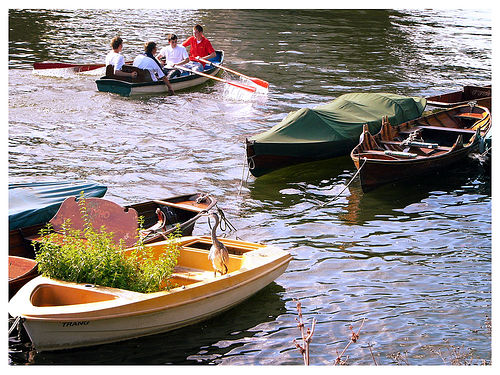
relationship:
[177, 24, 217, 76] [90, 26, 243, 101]
boy rowing boat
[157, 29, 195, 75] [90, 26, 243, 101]
guy rowing boat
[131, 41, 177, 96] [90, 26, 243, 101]
guy rowing boat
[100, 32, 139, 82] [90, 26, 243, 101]
guy rowing boat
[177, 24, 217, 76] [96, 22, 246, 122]
boy rowing boat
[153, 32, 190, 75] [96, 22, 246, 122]
guy rowing boat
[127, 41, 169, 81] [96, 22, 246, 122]
guy rowing boat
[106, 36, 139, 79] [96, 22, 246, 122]
guy rowing boat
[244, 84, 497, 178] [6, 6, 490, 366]
boat in lake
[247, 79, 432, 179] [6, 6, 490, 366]
boat in lake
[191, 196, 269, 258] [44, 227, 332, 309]
bird standing in boat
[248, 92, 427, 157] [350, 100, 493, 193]
cover on boat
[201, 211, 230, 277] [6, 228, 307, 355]
bird standing on boat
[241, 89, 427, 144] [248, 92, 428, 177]
cover on boat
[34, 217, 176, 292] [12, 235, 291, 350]
foliage in boat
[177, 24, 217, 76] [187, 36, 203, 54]
boy wearing shirt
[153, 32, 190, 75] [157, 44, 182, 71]
guy wearing shirt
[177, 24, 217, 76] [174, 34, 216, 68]
boy wearing shirt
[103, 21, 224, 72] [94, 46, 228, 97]
family using rowboat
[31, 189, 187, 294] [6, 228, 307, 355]
foliage in boat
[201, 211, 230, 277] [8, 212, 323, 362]
bird in boat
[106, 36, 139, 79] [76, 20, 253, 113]
guy in boat